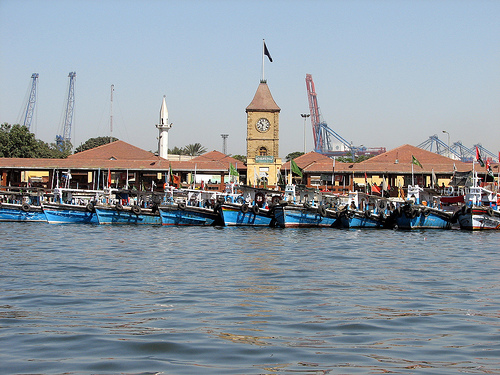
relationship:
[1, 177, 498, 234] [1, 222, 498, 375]
boats aligned in ocean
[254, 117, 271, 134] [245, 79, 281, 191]
clock has building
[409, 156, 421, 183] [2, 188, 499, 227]
flag near boats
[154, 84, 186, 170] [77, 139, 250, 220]
tower behind building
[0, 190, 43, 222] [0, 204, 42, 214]
boat has stripe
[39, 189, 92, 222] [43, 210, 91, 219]
boat has stripe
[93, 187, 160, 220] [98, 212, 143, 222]
boat has stripe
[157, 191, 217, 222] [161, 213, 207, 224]
boat has stripe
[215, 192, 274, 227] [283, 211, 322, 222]
boat has stripe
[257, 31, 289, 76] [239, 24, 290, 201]
flag atop tower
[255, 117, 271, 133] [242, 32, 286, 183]
clock atop tower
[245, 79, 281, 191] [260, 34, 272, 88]
building has flag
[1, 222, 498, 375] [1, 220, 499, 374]
ocean are in ocean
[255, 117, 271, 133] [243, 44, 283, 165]
clock on tower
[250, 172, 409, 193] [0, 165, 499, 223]
people on dock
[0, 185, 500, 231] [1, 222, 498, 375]
boats in ocean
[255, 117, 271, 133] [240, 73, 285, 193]
clock on tower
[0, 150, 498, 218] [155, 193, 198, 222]
structure behind boat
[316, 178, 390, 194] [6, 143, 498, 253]
flag on boats